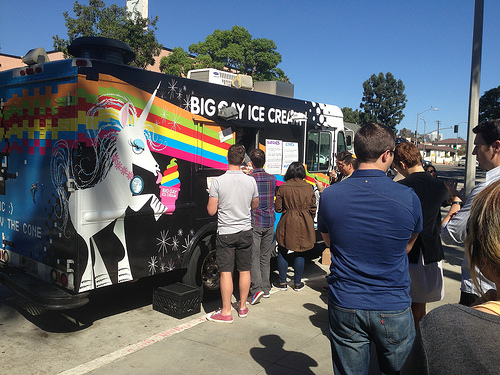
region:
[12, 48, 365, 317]
A black ice cream truck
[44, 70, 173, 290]
A white unicorn design on ice cream truck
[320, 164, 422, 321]
A navy blue tee shirt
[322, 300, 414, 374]
A pair of blue jeans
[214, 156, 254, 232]
A gray tee shirt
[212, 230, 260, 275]
A black pair of shorts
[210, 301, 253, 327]
A red pair of tennis shoes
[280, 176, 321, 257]
A dark brown coat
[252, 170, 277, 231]
A blue and red plaid shirt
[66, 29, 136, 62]
A black vent on top of ice cream truck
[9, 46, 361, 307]
Large ice cream truck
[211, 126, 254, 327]
Person standing on pavement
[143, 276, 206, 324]
Small black crate on pavement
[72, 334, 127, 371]
Small part of pavement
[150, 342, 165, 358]
Small part of pavement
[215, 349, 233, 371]
Small part of pavement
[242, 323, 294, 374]
Black shadow on pavement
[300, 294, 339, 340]
Black shadow on pavement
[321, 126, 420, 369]
Person standing on pavement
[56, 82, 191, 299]
Very colorful icecream held by unicorn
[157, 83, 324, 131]
name of the shop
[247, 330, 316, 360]
shadow of the person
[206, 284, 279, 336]
legs of the person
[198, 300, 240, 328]
shoe of the person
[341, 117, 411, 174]
face of the person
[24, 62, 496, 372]
a group of people standing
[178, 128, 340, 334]
a group of people watching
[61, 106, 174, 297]
a beautiful horse art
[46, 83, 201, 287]
a nice design before shop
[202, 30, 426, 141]
a clear view of trees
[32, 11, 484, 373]
Photo taken during the day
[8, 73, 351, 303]
Black ice cream truck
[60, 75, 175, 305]
Unicorn on the truck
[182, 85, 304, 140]
BIG GAY ICE CREAM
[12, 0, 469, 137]
The sky is clear and blue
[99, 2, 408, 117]
Green leaves on the trees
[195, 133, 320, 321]
People ordering from the ice cream truck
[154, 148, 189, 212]
Rainbow ice cream cone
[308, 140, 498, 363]
People waiting in line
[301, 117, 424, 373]
Man in jeans and a blue shirt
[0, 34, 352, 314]
colorful ice cream truck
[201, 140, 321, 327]
three people waiting in line for ice cream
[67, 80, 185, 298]
unicorn on truck licking ice cream cone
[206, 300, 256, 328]
man wearing pink tennis shoes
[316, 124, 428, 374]
back of man in blue shirt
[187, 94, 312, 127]
name of ice cream truck in white letters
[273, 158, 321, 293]
woman in brown coat deciding what to order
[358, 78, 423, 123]
large tree with green leaves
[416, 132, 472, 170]
houses with brown roofs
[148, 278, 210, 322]
black crate sitting under ice cream truck